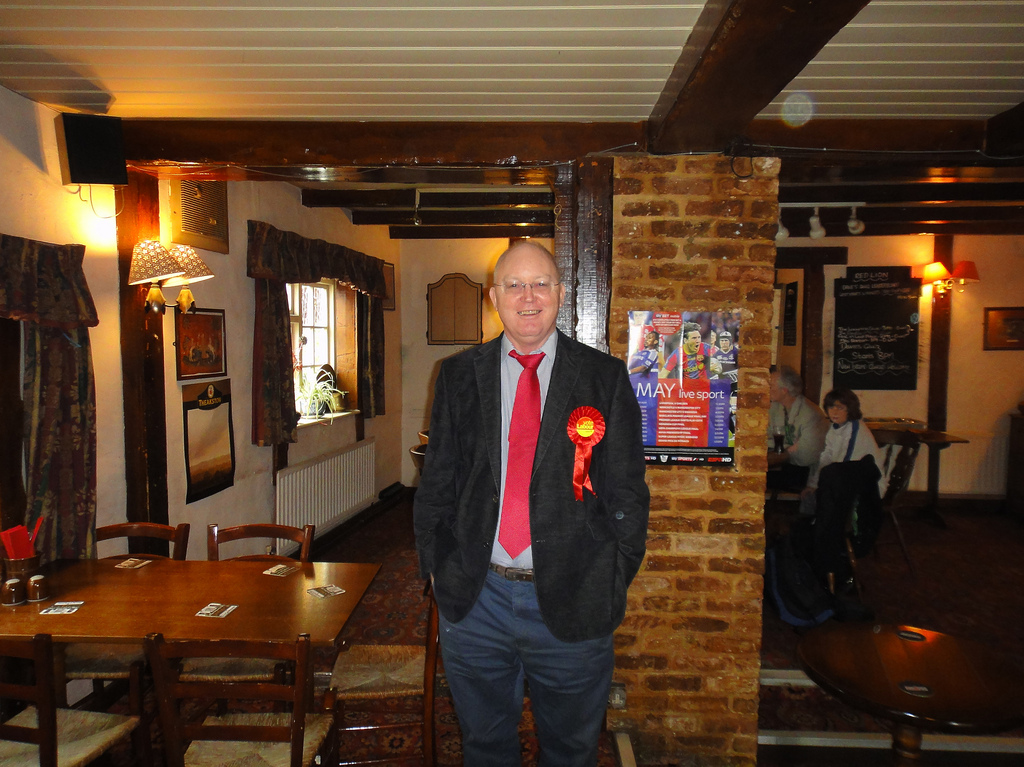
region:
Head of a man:
[479, 234, 575, 349]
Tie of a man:
[492, 346, 549, 562]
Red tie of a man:
[498, 346, 549, 558]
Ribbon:
[561, 405, 607, 508]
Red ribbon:
[560, 399, 612, 504]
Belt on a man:
[484, 558, 539, 590]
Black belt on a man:
[479, 557, 537, 586]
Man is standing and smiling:
[476, 234, 574, 351]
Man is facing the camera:
[478, 238, 571, 359]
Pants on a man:
[427, 555, 611, 765]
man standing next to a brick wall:
[412, 153, 779, 760]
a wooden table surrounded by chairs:
[8, 519, 438, 766]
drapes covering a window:
[244, 219, 384, 447]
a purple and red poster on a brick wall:
[607, 157, 782, 765]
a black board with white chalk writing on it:
[832, 268, 919, 393]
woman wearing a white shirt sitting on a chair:
[811, 391, 919, 575]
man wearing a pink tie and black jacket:
[415, 242, 650, 759]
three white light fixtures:
[775, 197, 867, 246]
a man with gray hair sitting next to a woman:
[766, 363, 921, 566]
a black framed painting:
[169, 303, 227, 379]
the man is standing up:
[415, 239, 646, 765]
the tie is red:
[495, 347, 546, 560]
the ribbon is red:
[564, 405, 602, 507]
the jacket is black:
[415, 325, 650, 643]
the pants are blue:
[430, 558, 615, 758]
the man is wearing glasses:
[415, 241, 651, 764]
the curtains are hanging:
[242, 215, 392, 449]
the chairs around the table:
[4, 518, 439, 763]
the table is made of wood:
[1, 557, 382, 763]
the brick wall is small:
[599, 151, 781, 765]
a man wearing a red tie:
[488, 349, 562, 556]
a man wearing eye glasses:
[490, 272, 567, 301]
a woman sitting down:
[812, 386, 889, 482]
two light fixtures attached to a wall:
[131, 231, 202, 320]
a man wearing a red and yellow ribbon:
[561, 398, 626, 501]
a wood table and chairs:
[4, 516, 387, 764]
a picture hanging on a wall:
[163, 301, 233, 381]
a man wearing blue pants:
[449, 560, 627, 723]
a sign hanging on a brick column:
[627, 294, 744, 460]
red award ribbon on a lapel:
[561, 399, 610, 511]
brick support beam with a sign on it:
[592, 130, 780, 761]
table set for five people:
[0, 509, 440, 760]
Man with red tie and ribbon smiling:
[412, 240, 650, 757]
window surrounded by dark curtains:
[235, 212, 388, 440]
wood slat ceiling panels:
[5, 3, 1008, 144]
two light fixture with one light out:
[918, 243, 983, 307]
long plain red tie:
[491, 345, 548, 567]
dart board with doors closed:
[422, 268, 486, 349]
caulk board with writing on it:
[823, 266, 923, 403]